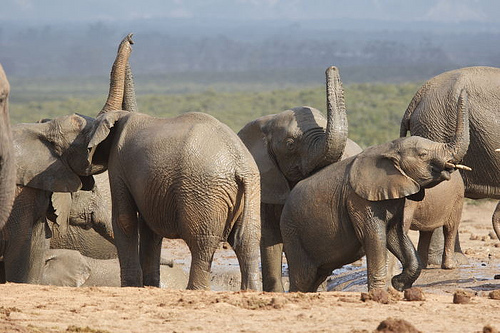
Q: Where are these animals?
A: Near a watering hole.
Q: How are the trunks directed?
A: Upward.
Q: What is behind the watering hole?
A: Grass.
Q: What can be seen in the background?
A: Trees covered by fog.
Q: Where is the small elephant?
A: To the right.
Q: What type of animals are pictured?
A: Elephants.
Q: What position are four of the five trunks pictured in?
A: Up in the air.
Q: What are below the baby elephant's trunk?
A: Tusks.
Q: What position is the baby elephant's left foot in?
A: Bent at the knee.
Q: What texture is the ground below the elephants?
A: Muddy.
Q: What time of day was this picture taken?
A: During daylight hours.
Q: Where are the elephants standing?
A: In a mudpit.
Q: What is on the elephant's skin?
A: Mud.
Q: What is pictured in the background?
A: Hills.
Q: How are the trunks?
A: Raised.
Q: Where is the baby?
A: Mud.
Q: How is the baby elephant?
A: Standing.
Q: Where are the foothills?
A: Distance.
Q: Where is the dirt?
A: Under elephants.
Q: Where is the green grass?
A: Field.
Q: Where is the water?
A: Puddle.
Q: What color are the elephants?
A: Gray.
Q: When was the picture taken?
A: Daytime.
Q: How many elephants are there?
A: Seven.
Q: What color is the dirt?
A: Brown.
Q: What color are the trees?
A: Green.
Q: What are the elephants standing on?
A: Dirt.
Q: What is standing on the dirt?
A: The elephants.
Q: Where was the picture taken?
A: At a water hole in a grassy plain.